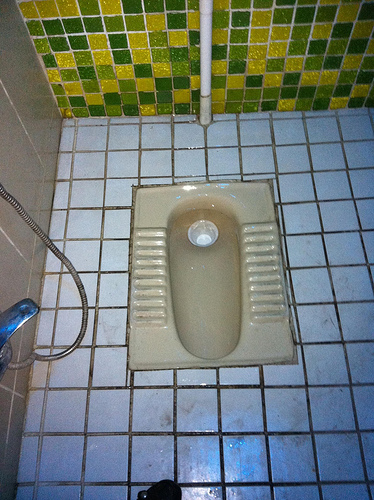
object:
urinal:
[128, 181, 294, 372]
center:
[187, 219, 219, 247]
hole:
[187, 219, 220, 248]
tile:
[132, 388, 174, 432]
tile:
[177, 388, 217, 433]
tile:
[269, 434, 318, 485]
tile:
[174, 435, 221, 481]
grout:
[21, 430, 374, 434]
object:
[135, 479, 182, 498]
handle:
[0, 298, 39, 350]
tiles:
[132, 8, 196, 114]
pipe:
[198, 0, 213, 128]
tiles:
[40, 14, 90, 78]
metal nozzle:
[15, 190, 75, 312]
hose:
[0, 186, 88, 370]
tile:
[92, 346, 127, 386]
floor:
[17, 110, 374, 500]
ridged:
[302, 146, 315, 171]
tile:
[105, 179, 138, 208]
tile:
[74, 117, 107, 151]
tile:
[208, 146, 240, 175]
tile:
[241, 145, 276, 174]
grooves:
[164, 197, 242, 360]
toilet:
[0, 0, 374, 500]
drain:
[187, 219, 219, 248]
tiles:
[339, 159, 371, 191]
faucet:
[0, 297, 40, 378]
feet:
[242, 221, 287, 324]